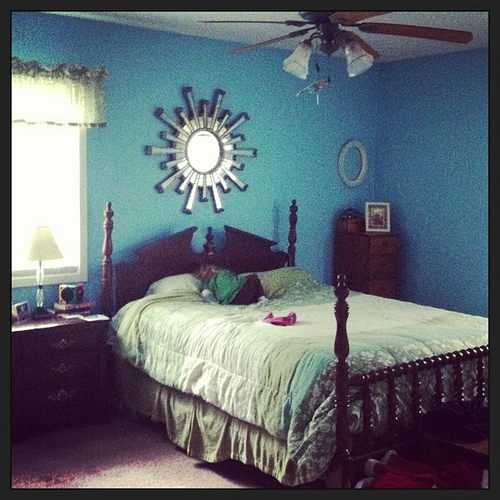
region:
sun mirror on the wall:
[143, 85, 260, 217]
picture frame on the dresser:
[364, 200, 390, 232]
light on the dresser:
[24, 226, 64, 321]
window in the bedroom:
[8, 73, 90, 284]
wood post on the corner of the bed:
[331, 272, 358, 491]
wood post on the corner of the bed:
[96, 199, 114, 389]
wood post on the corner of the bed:
[285, 197, 305, 267]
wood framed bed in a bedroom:
[93, 196, 490, 489]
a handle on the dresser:
[48, 335, 75, 351]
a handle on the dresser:
[51, 360, 76, 373]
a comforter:
[355, 305, 417, 340]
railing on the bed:
[358, 353, 495, 410]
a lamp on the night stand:
[23, 229, 63, 319]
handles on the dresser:
[48, 337, 80, 404]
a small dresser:
[340, 233, 397, 280]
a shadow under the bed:
[219, 467, 248, 487]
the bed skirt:
[163, 400, 214, 447]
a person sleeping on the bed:
[196, 263, 273, 307]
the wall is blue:
[104, 162, 130, 198]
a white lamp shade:
[23, 232, 61, 261]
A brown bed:
[90, 199, 490, 458]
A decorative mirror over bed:
[142, 76, 267, 211]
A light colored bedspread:
[145, 270, 331, 460]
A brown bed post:
[81, 200, 131, 315]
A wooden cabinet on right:
[332, 197, 392, 288]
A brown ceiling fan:
[247, 23, 474, 116]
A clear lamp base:
[22, 260, 54, 315]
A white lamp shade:
[15, 216, 65, 266]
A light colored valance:
[11, 47, 112, 139]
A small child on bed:
[191, 260, 275, 310]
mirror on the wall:
[337, 132, 369, 187]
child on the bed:
[197, 259, 271, 307]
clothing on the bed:
[255, 311, 298, 325]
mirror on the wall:
[143, 84, 260, 214]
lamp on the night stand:
[25, 221, 62, 319]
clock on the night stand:
[59, 282, 84, 303]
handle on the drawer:
[45, 335, 72, 346]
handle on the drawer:
[48, 365, 77, 376]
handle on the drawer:
[46, 389, 78, 401]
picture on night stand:
[12, 299, 32, 326]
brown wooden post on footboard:
[359, 381, 375, 450]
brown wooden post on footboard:
[384, 376, 401, 436]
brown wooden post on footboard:
[411, 373, 422, 433]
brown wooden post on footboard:
[433, 370, 441, 407]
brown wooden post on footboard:
[453, 364, 465, 398]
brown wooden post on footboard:
[476, 359, 483, 405]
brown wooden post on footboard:
[334, 270, 351, 456]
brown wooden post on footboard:
[353, 336, 483, 385]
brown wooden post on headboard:
[99, 201, 118, 319]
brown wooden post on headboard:
[287, 196, 299, 266]